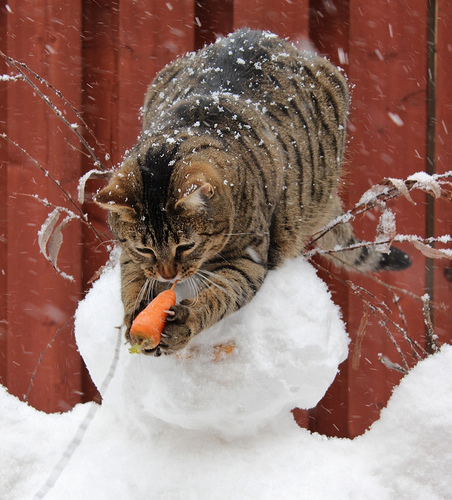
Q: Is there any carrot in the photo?
A: Yes, there is a carrot.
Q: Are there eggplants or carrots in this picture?
A: Yes, there is a carrot.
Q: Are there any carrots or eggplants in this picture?
A: Yes, there is a carrot.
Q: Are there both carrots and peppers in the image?
A: No, there is a carrot but no peppers.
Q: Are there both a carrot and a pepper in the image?
A: No, there is a carrot but no peppers.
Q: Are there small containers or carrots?
A: Yes, there is a small carrot.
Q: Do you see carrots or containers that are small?
A: Yes, the carrot is small.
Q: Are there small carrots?
A: Yes, there is a small carrot.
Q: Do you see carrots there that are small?
A: Yes, there is a carrot that is small.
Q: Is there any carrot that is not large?
A: Yes, there is a small carrot.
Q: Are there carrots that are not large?
A: Yes, there is a small carrot.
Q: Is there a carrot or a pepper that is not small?
A: No, there is a carrot but it is small.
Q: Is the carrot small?
A: Yes, the carrot is small.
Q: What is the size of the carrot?
A: The carrot is small.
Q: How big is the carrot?
A: The carrot is small.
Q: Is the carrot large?
A: No, the carrot is small.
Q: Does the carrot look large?
A: No, the carrot is small.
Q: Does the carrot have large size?
A: No, the carrot is small.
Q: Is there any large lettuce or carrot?
A: No, there is a carrot but it is small.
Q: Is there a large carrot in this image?
A: No, there is a carrot but it is small.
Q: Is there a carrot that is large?
A: No, there is a carrot but it is small.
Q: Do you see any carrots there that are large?
A: No, there is a carrot but it is small.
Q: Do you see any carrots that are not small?
A: No, there is a carrot but it is small.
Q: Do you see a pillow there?
A: No, there are no pillows.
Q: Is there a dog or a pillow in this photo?
A: No, there are no pillows or dogs.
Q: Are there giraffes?
A: No, there are no giraffes.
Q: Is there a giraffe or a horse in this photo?
A: No, there are no giraffes or horses.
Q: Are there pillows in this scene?
A: No, there are no pillows.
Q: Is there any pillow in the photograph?
A: No, there are no pillows.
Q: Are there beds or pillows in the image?
A: No, there are no pillows or beds.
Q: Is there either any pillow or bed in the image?
A: No, there are no pillows or beds.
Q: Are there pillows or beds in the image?
A: No, there are no pillows or beds.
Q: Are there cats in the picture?
A: Yes, there is a cat.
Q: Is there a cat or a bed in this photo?
A: Yes, there is a cat.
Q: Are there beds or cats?
A: Yes, there is a cat.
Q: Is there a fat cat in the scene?
A: Yes, there is a fat cat.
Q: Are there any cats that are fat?
A: Yes, there is a cat that is fat.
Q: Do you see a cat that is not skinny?
A: Yes, there is a fat cat.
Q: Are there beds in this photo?
A: No, there are no beds.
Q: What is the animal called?
A: The animal is a cat.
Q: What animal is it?
A: The animal is a cat.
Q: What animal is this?
A: This is a cat.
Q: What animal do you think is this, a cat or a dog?
A: This is a cat.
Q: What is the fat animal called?
A: The animal is a cat.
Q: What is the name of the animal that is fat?
A: The animal is a cat.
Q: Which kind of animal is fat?
A: The animal is a cat.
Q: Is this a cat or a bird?
A: This is a cat.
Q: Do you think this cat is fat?
A: Yes, the cat is fat.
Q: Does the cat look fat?
A: Yes, the cat is fat.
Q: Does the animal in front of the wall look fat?
A: Yes, the cat is fat.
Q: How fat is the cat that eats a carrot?
A: The cat is fat.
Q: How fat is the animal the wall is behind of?
A: The cat is fat.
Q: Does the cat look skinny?
A: No, the cat is fat.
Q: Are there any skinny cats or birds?
A: No, there is a cat but it is fat.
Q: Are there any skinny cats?
A: No, there is a cat but it is fat.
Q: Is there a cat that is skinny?
A: No, there is a cat but it is fat.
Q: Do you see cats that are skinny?
A: No, there is a cat but it is fat.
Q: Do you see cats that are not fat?
A: No, there is a cat but it is fat.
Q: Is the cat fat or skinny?
A: The cat is fat.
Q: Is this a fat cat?
A: Yes, this is a fat cat.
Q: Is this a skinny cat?
A: No, this is a fat cat.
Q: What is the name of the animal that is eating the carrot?
A: The animal is a cat.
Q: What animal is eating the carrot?
A: The animal is a cat.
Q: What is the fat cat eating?
A: The cat is eating a carrot.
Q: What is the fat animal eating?
A: The cat is eating a carrot.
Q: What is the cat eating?
A: The cat is eating a carrot.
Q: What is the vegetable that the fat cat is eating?
A: The vegetable is a carrot.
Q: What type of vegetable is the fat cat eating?
A: The cat is eating a carrot.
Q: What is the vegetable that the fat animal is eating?
A: The vegetable is a carrot.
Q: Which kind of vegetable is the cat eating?
A: The cat is eating a carrot.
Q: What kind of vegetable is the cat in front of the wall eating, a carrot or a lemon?
A: The cat is eating a carrot.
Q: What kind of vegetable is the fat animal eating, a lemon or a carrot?
A: The cat is eating a carrot.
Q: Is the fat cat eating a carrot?
A: Yes, the cat is eating a carrot.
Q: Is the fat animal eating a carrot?
A: Yes, the cat is eating a carrot.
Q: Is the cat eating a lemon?
A: No, the cat is eating a carrot.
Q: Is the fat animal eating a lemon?
A: No, the cat is eating a carrot.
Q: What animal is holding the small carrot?
A: The cat is holding the carrot.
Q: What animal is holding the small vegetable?
A: The cat is holding the carrot.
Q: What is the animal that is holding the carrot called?
A: The animal is a cat.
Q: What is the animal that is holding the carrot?
A: The animal is a cat.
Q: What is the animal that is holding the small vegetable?
A: The animal is a cat.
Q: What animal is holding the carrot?
A: The animal is a cat.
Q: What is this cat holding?
A: The cat is holding the carrot.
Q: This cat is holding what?
A: The cat is holding the carrot.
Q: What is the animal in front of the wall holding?
A: The cat is holding the carrot.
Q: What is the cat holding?
A: The cat is holding the carrot.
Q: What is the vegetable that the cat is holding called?
A: The vegetable is a carrot.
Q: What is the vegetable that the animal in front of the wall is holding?
A: The vegetable is a carrot.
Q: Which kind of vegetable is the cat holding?
A: The cat is holding the carrot.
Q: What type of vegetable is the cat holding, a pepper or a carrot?
A: The cat is holding a carrot.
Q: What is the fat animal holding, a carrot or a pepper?
A: The cat is holding a carrot.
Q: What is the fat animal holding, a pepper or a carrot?
A: The cat is holding a carrot.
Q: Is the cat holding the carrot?
A: Yes, the cat is holding the carrot.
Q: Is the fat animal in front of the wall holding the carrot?
A: Yes, the cat is holding the carrot.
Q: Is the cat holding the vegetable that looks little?
A: Yes, the cat is holding the carrot.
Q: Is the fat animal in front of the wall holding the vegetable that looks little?
A: Yes, the cat is holding the carrot.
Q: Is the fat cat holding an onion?
A: No, the cat is holding the carrot.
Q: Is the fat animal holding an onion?
A: No, the cat is holding the carrot.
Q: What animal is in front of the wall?
A: The cat is in front of the wall.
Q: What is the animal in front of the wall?
A: The animal is a cat.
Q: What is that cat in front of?
A: The cat is in front of the wall.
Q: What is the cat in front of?
A: The cat is in front of the wall.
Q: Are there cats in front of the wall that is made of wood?
A: Yes, there is a cat in front of the wall.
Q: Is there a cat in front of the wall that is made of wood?
A: Yes, there is a cat in front of the wall.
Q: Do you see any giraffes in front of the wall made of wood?
A: No, there is a cat in front of the wall.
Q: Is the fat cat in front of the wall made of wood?
A: Yes, the cat is in front of the wall.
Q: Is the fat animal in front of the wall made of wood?
A: Yes, the cat is in front of the wall.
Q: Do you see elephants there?
A: No, there are no elephants.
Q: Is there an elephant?
A: No, there are no elephants.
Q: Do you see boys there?
A: No, there are no boys.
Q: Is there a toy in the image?
A: No, there are no toys.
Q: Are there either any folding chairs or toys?
A: No, there are no toys or folding chairs.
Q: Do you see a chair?
A: No, there are no chairs.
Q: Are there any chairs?
A: No, there are no chairs.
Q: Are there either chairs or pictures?
A: No, there are no chairs or pictures.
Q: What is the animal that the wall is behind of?
A: The animal is a cat.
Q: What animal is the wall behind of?
A: The wall is behind the cat.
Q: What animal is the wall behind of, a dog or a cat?
A: The wall is behind a cat.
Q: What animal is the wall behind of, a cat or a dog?
A: The wall is behind a cat.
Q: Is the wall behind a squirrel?
A: No, the wall is behind a cat.